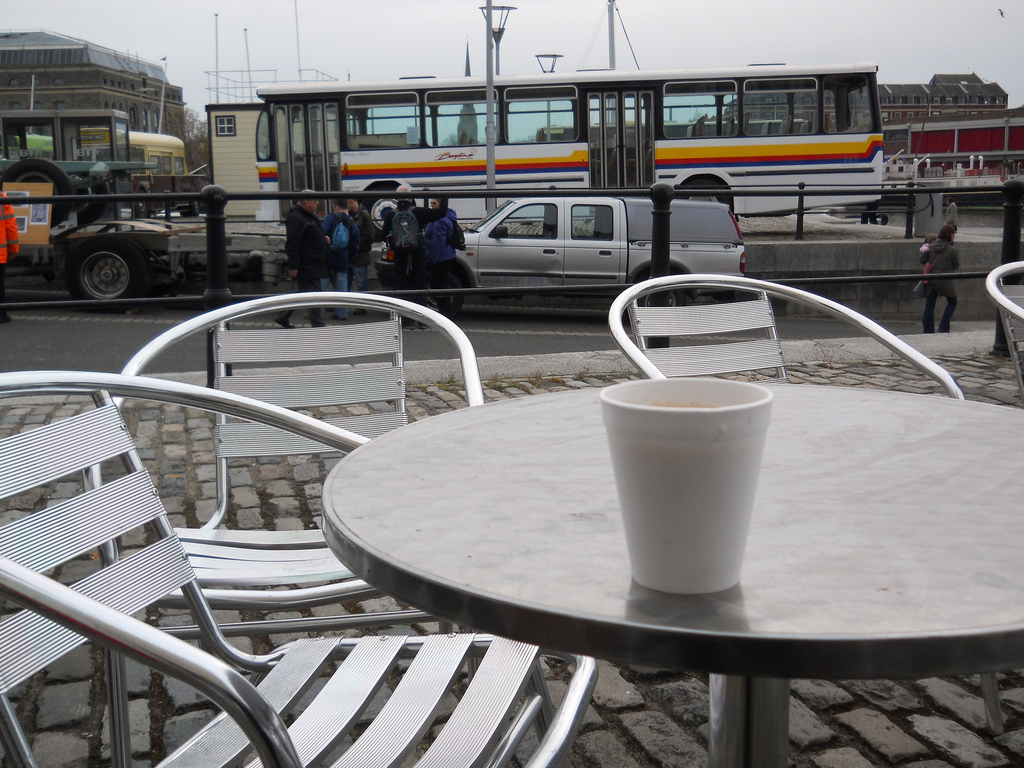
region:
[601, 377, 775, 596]
the cup is white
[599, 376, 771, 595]
the styrofoam cup is white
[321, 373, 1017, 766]
the table is round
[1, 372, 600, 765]
the chair is made of metal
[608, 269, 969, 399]
the chair is silver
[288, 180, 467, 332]
the people standing in a group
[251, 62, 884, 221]
the bus has colorful stripes on the side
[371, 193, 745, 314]
the truck is gray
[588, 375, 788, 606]
Small white styrofoam cup.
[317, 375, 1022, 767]
Round metal silver table.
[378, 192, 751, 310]
Parked silver truck.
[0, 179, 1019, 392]
Black iron fence alongside road.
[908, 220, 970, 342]
Woman carrying a child.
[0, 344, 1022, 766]
Brown brick uneven terrace.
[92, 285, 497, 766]
Shiny silver metal chair.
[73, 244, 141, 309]
Black tire with silver rim.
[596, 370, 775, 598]
white styrofoam cup on a table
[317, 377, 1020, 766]
circular shiny silver metal table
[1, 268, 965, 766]
three shiny silver metal outdoor chairs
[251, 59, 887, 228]
white bus with colorful stripe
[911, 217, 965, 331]
woman carrying a baby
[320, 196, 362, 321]
person wearing blue backpack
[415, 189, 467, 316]
woman carrying black purse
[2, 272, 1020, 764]
shiny metal table and chair set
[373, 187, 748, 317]
old silver pickup truck with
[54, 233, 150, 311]
large black wheel with silver rim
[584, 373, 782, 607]
white Styrofoam cup sitting on the table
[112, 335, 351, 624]
silver metal chair at the table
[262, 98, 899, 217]
bus parked in the lot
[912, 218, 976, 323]
person carrying a small child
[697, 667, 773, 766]
silver metal post of the table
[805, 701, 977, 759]
brick sidewalk under the table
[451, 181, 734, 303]
truck is parked by the bus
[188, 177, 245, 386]
black metal post of the railing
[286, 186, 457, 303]
people standing in the lot behind the table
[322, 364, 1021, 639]
table on the brick sidewalk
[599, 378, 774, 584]
an empty white Styrofoam cup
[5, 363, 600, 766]
a shiny metal chair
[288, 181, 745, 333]
people gathered next to a silver car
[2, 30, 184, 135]
a brown building in the distance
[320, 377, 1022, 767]
a silver round table on a silver central leg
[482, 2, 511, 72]
a black street lamp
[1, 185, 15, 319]
man wearing an orange security coat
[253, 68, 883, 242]
a white bus with colorful lines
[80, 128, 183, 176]
a small yellow bus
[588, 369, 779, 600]
white paper cup on outdoor metal table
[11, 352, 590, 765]
a chair that you sit in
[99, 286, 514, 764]
a chair that you sit in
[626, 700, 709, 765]
a brick in a sidewalk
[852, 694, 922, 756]
a brick in a sidewalk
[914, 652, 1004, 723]
a brick in a sidewalk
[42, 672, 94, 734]
a brick in a sidewalk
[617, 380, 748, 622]
the cup is white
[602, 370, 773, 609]
the cup is styrofoam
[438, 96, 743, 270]
the truck is beside the bus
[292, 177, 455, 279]
the people are standing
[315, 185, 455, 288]
the people are in the crowd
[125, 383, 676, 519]
the path is brick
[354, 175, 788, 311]
the people are by the car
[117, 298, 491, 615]
the chair is silver